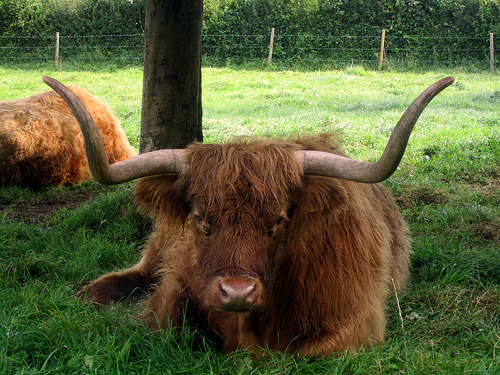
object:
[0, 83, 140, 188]
bull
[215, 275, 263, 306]
nose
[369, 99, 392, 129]
ground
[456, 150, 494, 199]
grass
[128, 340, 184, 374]
grass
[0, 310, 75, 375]
grass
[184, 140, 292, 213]
hair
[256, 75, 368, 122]
grass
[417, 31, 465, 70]
wires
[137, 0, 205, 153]
tree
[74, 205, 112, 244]
green grass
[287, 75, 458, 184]
gray horn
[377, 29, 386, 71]
post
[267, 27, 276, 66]
post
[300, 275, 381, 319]
fur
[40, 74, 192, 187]
horn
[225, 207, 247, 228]
part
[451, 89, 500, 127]
ground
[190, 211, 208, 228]
eye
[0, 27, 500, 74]
fence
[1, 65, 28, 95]
ground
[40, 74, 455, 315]
head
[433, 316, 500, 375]
grass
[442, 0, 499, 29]
bushes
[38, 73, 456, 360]
animal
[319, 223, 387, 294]
fur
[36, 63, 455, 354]
animal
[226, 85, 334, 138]
light